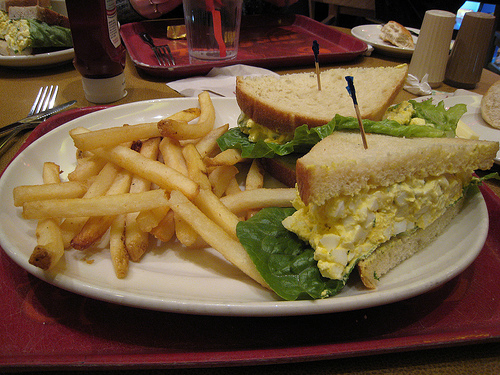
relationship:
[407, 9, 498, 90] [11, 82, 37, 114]
bottles on table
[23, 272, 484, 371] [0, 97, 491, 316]
shadow from dish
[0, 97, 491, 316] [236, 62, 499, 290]
dish with egg sandwich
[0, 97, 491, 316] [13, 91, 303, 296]
dish with french fries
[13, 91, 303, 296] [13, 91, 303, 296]
french fries next to french fries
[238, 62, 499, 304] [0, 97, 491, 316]
egg sandwich on dish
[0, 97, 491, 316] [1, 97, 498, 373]
dish on tray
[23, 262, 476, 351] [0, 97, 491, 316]
shadow of dish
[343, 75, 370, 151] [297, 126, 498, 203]
tooth pick in bread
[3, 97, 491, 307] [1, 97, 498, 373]
dish sitting on tray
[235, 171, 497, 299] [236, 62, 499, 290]
leaf about egg sandwich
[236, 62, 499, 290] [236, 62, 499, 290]
egg sandwich has egg sandwich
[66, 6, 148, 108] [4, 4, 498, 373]
bottle on table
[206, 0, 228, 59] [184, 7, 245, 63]
straw on glass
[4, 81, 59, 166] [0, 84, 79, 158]
fork underneath fork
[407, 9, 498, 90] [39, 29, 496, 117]
bottles on table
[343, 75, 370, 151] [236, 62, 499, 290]
tooth pick in egg sandwich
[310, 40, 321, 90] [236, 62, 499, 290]
toothpick in egg sandwich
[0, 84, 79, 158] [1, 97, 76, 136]
fork on top of fork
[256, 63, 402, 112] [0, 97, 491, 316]
bread on dish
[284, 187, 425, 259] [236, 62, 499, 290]
egg inside egg sandwich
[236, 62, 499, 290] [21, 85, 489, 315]
egg sandwich on dish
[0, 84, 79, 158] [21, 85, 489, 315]
fork on side of dish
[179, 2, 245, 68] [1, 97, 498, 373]
glass on tray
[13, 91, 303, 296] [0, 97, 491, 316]
french fries on dish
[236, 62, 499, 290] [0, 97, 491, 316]
egg sandwich on dish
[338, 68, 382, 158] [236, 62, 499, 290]
tooth pick in egg sandwich